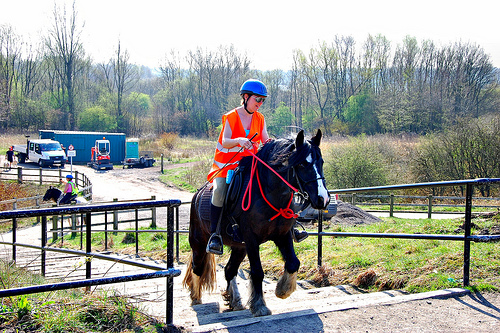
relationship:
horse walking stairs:
[181, 128, 332, 317] [26, 232, 386, 309]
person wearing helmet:
[208, 78, 308, 251] [239, 77, 268, 96]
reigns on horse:
[242, 145, 302, 221] [181, 128, 332, 317]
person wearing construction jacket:
[208, 78, 308, 251] [206, 106, 265, 183]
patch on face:
[297, 154, 327, 202] [281, 123, 342, 222]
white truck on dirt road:
[15, 138, 67, 167] [0, 158, 189, 200]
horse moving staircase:
[176, 143, 374, 315] [138, 246, 467, 331]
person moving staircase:
[208, 78, 308, 251] [138, 246, 467, 331]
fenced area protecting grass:
[49, 211, 498, 291] [65, 210, 480, 270]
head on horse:
[279, 129, 344, 224] [184, 127, 337, 320]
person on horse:
[208, 78, 308, 251] [178, 128, 334, 309]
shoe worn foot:
[203, 231, 225, 254] [206, 231, 225, 256]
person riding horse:
[205, 78, 309, 253] [181, 128, 332, 317]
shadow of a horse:
[183, 299, 330, 331] [183, 130, 323, 313]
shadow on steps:
[183, 299, 330, 331] [32, 249, 499, 329]